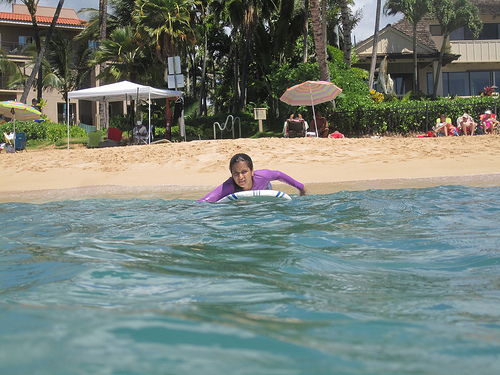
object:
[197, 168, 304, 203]
wetsuit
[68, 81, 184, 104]
awning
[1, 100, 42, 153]
umbrella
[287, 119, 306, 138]
chair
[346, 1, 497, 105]
house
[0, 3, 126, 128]
house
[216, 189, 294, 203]
board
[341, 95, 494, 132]
bushes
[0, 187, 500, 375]
water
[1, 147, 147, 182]
sand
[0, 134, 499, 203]
beach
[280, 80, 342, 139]
umbrella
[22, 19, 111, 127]
palms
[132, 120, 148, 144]
man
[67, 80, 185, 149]
posts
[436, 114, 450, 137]
people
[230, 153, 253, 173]
hair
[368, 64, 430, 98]
entrance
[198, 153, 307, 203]
woman